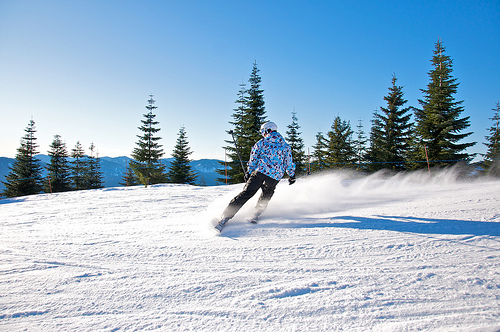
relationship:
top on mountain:
[118, 152, 129, 162] [0, 150, 234, 203]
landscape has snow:
[2, 40, 500, 331] [1, 177, 499, 331]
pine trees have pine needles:
[0, 33, 499, 197] [427, 109, 447, 129]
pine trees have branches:
[0, 33, 499, 197] [149, 99, 163, 158]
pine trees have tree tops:
[0, 33, 499, 197] [128, 34, 468, 110]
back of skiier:
[250, 139, 290, 177] [210, 118, 299, 238]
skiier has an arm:
[210, 118, 299, 238] [280, 144, 298, 188]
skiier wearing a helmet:
[210, 118, 299, 238] [256, 120, 279, 139]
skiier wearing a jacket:
[210, 118, 299, 238] [240, 132, 298, 183]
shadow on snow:
[263, 210, 499, 245] [1, 177, 499, 331]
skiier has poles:
[210, 118, 299, 238] [228, 127, 254, 179]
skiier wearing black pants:
[210, 118, 299, 238] [221, 168, 281, 220]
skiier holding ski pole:
[210, 118, 299, 238] [228, 127, 254, 179]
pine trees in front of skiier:
[0, 33, 499, 197] [210, 118, 299, 238]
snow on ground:
[1, 177, 499, 331] [1, 179, 497, 332]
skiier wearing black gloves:
[210, 118, 299, 238] [285, 172, 298, 187]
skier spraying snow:
[210, 118, 299, 238] [1, 177, 499, 331]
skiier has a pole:
[210, 118, 299, 238] [218, 123, 256, 186]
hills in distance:
[0, 146, 242, 194] [1, 102, 499, 194]